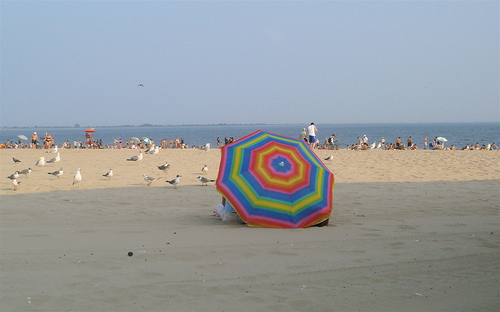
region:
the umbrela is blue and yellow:
[224, 133, 353, 224]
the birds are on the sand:
[28, 148, 205, 192]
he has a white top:
[305, 113, 324, 148]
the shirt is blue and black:
[302, 134, 316, 144]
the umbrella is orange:
[83, 123, 97, 135]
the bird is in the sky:
[128, 76, 149, 90]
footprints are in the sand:
[371, 148, 435, 173]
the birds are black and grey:
[25, 152, 195, 187]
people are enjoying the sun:
[14, 129, 189, 155]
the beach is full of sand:
[60, 193, 184, 275]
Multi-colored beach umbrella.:
[207, 124, 353, 234]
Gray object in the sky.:
[130, 77, 149, 94]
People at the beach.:
[2, 116, 496, 216]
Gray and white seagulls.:
[9, 143, 364, 201]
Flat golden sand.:
[11, 152, 488, 284]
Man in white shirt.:
[306, 120, 324, 149]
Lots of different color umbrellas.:
[10, 125, 465, 235]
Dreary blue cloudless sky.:
[242, 20, 445, 97]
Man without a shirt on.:
[28, 128, 42, 150]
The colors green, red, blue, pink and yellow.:
[243, 137, 318, 209]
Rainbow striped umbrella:
[172, 117, 367, 228]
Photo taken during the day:
[10, 13, 490, 304]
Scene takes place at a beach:
[11, 13, 491, 303]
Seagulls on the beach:
[1, 125, 217, 197]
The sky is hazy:
[12, 12, 481, 119]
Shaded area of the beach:
[21, 165, 491, 305]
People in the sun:
[2, 125, 489, 150]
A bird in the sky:
[120, 75, 160, 95]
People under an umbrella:
[190, 130, 362, 243]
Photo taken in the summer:
[23, 17, 488, 301]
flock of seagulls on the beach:
[12, 151, 209, 186]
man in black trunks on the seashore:
[31, 133, 37, 145]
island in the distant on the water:
[71, 123, 183, 125]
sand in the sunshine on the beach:
[352, 151, 497, 177]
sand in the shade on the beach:
[347, 182, 499, 218]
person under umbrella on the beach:
[216, 198, 233, 222]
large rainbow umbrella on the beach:
[232, 143, 312, 223]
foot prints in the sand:
[348, 225, 435, 257]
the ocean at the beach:
[338, 124, 413, 134]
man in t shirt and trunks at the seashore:
[308, 122, 314, 144]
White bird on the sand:
[71, 167, 85, 185]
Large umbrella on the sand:
[216, 130, 334, 225]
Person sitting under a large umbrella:
[211, 190, 243, 227]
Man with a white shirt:
[308, 124, 317, 134]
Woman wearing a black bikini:
[43, 131, 53, 147]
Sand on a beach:
[35, 251, 499, 306]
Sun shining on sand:
[340, 150, 490, 174]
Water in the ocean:
[154, 125, 221, 143]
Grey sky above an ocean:
[38, 13, 488, 72]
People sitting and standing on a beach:
[348, 129, 498, 154]